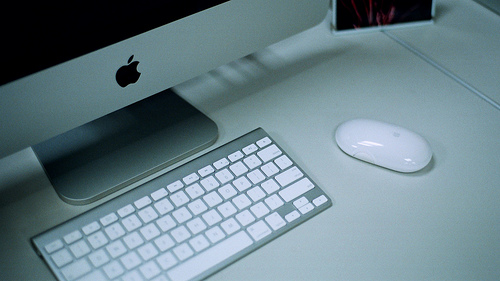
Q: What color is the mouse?
A: White.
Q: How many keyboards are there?
A: One.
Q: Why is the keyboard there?
A: So the user can type.